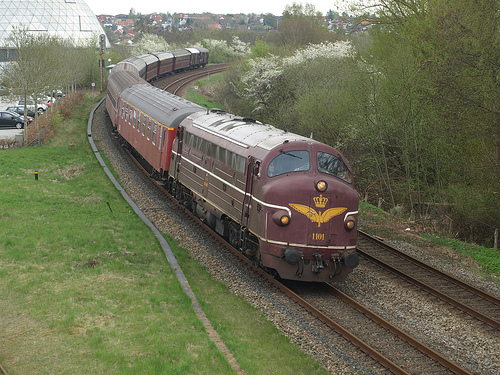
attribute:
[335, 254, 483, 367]
tracks — rusted, train 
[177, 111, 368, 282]
car — maroon lead train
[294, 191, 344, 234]
wings — yellow 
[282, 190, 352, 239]
crown — yellow 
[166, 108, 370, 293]
car — red train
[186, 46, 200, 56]
roof — white 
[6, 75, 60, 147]
lot — parking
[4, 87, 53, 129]
lot — parking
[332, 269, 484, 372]
tracks — rail road 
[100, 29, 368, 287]
train — side 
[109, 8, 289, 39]
houses — distance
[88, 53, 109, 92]
post — yellow ,  small black 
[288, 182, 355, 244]
sign — golden crown 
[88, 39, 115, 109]
light — tall signal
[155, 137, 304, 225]
line — white, at side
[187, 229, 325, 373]
grass — green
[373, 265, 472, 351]
stone — small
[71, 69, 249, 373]
steel — gray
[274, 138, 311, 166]
wiper — small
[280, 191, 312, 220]
wing — bird's, golden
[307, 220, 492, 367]
track — train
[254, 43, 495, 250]
trees — several, deciduous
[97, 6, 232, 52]
houses — several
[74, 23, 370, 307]
train — passenger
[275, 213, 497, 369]
track — rusty, rail road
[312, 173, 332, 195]
light — head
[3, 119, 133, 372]
grass — green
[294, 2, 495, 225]
trees — bunch, leafy, green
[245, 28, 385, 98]
trees — white, in bloom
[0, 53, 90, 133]
lot — parking